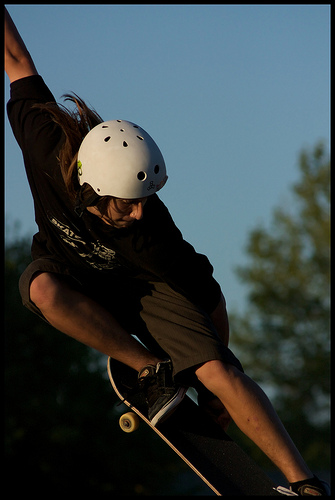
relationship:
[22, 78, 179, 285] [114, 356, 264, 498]
boy on skateboard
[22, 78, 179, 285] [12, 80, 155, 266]
boy wearing tshirt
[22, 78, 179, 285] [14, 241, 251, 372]
boy wearing shorts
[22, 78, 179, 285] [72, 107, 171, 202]
boy wearing helmet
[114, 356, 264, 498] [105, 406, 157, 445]
skateboard has wheels